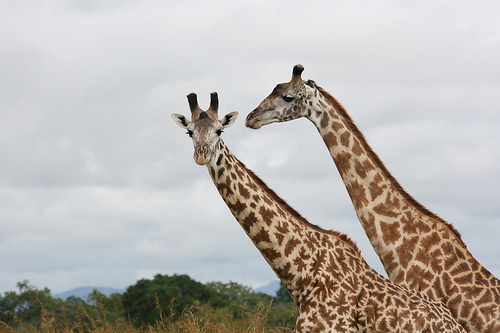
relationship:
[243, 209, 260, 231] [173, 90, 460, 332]
brown spot on giraffe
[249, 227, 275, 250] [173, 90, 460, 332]
spot on giraffe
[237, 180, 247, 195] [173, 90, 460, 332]
spot on giraffe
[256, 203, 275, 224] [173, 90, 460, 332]
spot on giraffe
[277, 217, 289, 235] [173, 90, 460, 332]
spot on giraffe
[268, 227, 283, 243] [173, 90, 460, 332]
spot on giraffe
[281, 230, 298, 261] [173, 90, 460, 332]
spot on giraffe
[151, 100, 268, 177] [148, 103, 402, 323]
head of giraffe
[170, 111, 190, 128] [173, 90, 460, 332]
ear of giraffe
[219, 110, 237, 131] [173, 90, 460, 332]
ear of giraffe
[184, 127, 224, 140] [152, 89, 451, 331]
eyes of giraffe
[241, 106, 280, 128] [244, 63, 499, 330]
mouth of giraffe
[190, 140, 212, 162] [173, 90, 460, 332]
mouth of giraffe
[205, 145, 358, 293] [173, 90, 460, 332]
neck of giraffe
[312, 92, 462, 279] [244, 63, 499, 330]
neck of giraffe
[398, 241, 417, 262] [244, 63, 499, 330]
brown spot on giraffe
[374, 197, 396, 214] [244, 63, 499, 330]
brown spot on giraffe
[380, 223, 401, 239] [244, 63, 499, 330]
brown spot on giraffe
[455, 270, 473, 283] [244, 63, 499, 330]
brown spot on giraffe